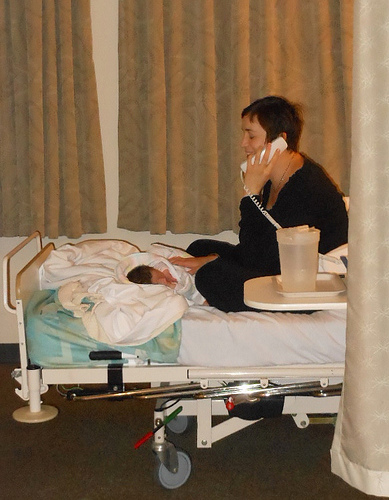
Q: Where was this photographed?
A: Hospital.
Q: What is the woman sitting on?
A: Hospital bed.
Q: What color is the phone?
A: White.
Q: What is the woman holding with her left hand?
A: Telephone.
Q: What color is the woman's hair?
A: Brown.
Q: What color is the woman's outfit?
A: Black.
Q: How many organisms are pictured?
A: Two.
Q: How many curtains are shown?
A: Two.